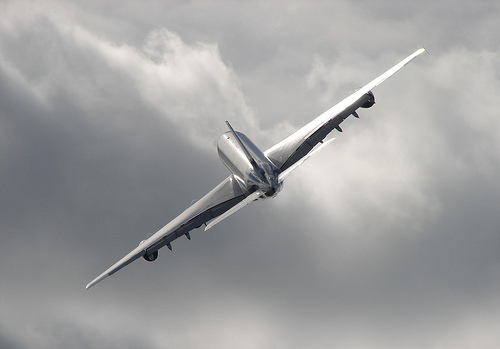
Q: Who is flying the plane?
A: Pilot.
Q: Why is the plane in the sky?
A: Flying.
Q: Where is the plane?
A: Sky.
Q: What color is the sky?
A: Gray.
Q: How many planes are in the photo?
A: One.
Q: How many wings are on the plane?
A: Two.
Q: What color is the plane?
A: Silver.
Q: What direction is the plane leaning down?
A: Left.